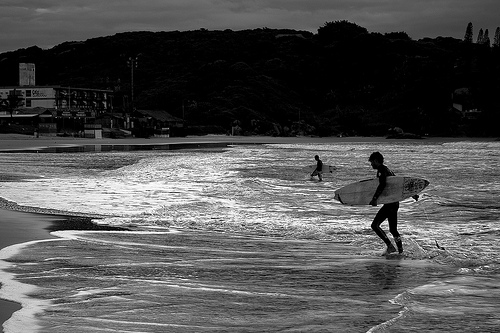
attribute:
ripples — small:
[429, 235, 489, 292]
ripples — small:
[426, 157, 494, 247]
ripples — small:
[235, 172, 312, 197]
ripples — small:
[198, 177, 495, 271]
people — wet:
[196, 140, 481, 305]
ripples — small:
[158, 214, 340, 274]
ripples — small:
[413, 228, 457, 260]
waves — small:
[227, 202, 379, 253]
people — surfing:
[299, 144, 408, 258]